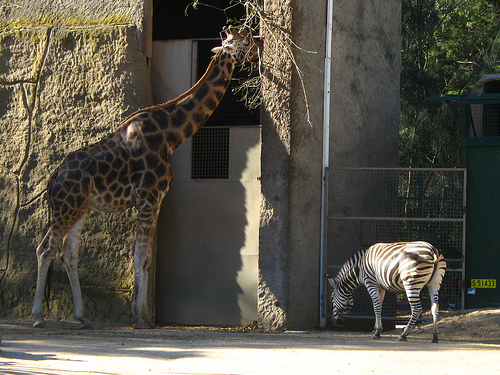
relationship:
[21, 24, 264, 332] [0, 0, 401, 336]
giraffe next building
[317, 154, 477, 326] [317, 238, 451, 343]
chain link behind zebra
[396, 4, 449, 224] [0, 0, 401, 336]
tree next building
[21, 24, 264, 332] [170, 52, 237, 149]
giraffe has neck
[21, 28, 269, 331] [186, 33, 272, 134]
giraffe close opening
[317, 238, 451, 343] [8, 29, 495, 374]
zebra in enclosure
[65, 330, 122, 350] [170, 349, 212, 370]
shadow on ground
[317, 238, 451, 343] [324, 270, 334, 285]
zebra has left ear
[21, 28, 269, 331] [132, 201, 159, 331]
giraffe has legs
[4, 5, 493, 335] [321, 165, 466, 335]
enclosure has fence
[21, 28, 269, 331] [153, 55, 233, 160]
giraffe has neck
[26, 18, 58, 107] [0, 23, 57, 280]
wall has crack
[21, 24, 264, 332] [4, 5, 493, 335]
giraffe in enclosure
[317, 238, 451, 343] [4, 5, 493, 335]
zebra in enclosure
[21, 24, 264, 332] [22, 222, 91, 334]
giraffe has legs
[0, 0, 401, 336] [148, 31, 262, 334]
building has door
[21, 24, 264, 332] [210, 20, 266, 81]
giraffe has head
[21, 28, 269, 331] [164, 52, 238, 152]
giraffe has neck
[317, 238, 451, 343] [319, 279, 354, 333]
zebra has head